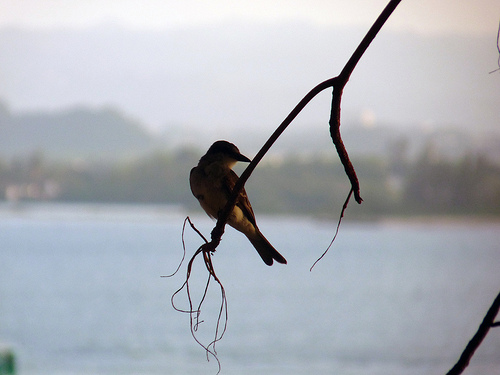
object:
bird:
[190, 140, 288, 267]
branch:
[159, 1, 402, 375]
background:
[0, 0, 499, 374]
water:
[0, 202, 499, 375]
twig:
[161, 217, 209, 277]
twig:
[172, 244, 202, 315]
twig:
[193, 251, 212, 331]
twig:
[207, 291, 229, 363]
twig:
[159, 215, 227, 375]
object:
[0, 351, 15, 375]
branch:
[445, 294, 499, 374]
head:
[198, 139, 253, 167]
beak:
[236, 153, 251, 162]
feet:
[215, 209, 232, 224]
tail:
[242, 223, 287, 265]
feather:
[242, 227, 288, 266]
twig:
[160, 77, 332, 375]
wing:
[224, 170, 256, 226]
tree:
[161, 1, 499, 375]